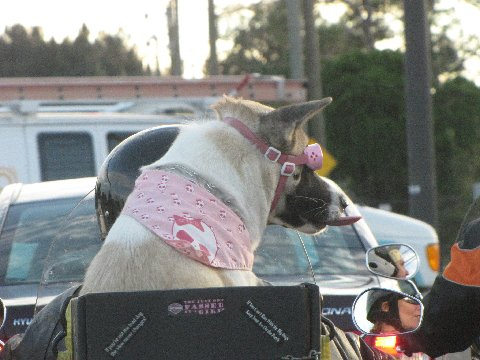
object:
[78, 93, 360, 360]
dog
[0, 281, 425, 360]
motorcycle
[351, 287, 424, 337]
mirror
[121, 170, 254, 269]
scarf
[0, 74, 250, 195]
van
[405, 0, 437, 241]
pole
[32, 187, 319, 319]
windshield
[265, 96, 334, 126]
ear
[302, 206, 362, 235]
mouth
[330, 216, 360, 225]
tongue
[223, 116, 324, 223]
goggles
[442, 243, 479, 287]
stripe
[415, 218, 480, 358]
jacket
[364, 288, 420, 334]
reflection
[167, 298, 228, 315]
sticker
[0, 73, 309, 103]
ladder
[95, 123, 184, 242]
helmet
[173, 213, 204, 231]
bow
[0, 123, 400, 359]
person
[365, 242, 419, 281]
mirror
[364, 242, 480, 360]
motorcycle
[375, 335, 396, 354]
light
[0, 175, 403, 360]
car